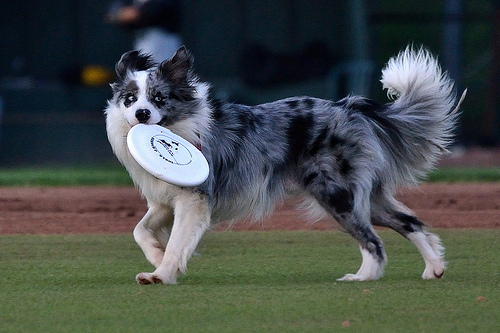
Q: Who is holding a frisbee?
A: Dog.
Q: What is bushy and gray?
A: Tail.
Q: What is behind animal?
A: Dirt.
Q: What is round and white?
A: Frisbee.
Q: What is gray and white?
A: Dog.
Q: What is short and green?
A: Grass.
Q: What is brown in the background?
A: Dirt.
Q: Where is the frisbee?
A: Dog's mouth.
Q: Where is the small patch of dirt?
A: Behind dog.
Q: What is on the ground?
A: Grass and dirt.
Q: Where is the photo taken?
A: In a field.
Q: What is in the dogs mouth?
A: A frisbee.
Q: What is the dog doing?
A: Running with a frisbee.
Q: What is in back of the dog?
A: A bushy tail.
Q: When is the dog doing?
A: Catching a frisbee.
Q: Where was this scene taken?
A: At a dog competition.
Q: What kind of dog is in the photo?
A: Australian shepherd.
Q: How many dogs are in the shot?
A: One.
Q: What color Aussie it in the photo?
A: A tri.